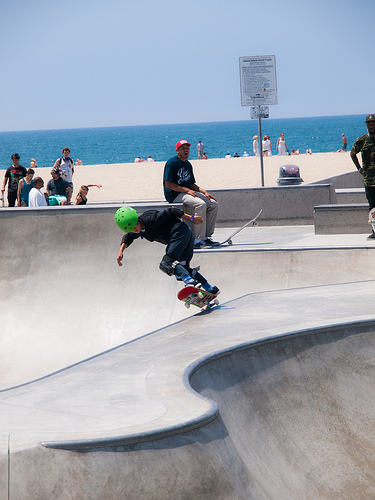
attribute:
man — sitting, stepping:
[159, 135, 223, 257]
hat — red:
[172, 137, 191, 151]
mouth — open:
[181, 152, 191, 157]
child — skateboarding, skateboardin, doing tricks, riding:
[110, 197, 220, 296]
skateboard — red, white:
[175, 282, 224, 313]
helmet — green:
[110, 204, 142, 234]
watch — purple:
[188, 213, 196, 226]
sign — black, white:
[235, 48, 286, 123]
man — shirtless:
[337, 130, 348, 153]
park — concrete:
[1, 157, 373, 499]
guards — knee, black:
[152, 255, 184, 280]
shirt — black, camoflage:
[161, 156, 201, 206]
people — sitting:
[27, 177, 48, 209]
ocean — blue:
[1, 112, 374, 172]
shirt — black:
[115, 200, 193, 249]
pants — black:
[156, 221, 209, 288]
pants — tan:
[171, 183, 220, 243]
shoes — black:
[195, 234, 221, 252]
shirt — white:
[261, 138, 271, 150]